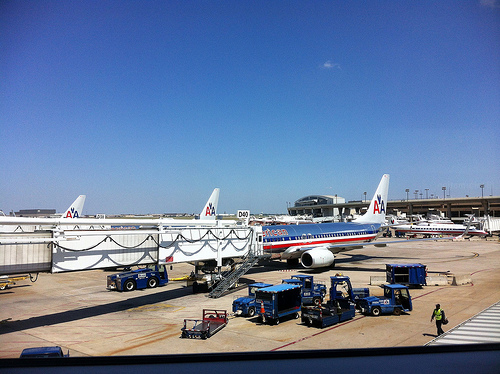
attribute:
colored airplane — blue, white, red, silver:
[255, 173, 390, 272]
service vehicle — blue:
[106, 260, 170, 290]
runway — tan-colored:
[1, 279, 191, 355]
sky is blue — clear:
[1, 2, 499, 216]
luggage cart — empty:
[180, 309, 228, 339]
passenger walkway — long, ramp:
[283, 255, 498, 350]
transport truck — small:
[358, 281, 414, 316]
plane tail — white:
[357, 173, 389, 221]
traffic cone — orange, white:
[179, 277, 194, 283]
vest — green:
[434, 310, 444, 322]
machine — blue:
[105, 258, 167, 289]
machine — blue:
[231, 283, 269, 315]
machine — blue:
[293, 275, 327, 306]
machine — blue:
[327, 273, 370, 307]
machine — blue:
[356, 282, 412, 314]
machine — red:
[179, 306, 231, 341]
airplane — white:
[392, 214, 469, 235]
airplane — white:
[198, 186, 221, 220]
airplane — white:
[56, 192, 86, 209]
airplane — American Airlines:
[63, 191, 87, 218]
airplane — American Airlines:
[196, 185, 222, 217]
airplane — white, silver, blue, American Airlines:
[254, 171, 392, 272]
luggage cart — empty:
[256, 280, 303, 322]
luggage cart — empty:
[385, 261, 426, 287]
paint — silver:
[265, 221, 384, 232]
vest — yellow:
[435, 309, 442, 320]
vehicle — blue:
[109, 262, 169, 290]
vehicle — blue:
[230, 280, 274, 317]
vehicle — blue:
[278, 273, 328, 305]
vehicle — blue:
[299, 272, 356, 327]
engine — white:
[296, 247, 337, 272]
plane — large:
[262, 171, 391, 270]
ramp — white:
[2, 209, 252, 278]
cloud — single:
[317, 51, 344, 77]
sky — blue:
[2, 2, 482, 219]